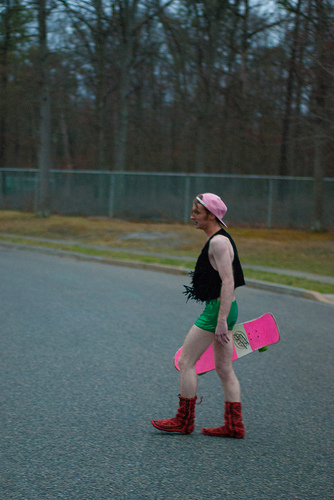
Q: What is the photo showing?
A: It is showing a road.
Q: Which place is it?
A: It is a road.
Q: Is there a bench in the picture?
A: No, there are no benches.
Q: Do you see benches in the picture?
A: No, there are no benches.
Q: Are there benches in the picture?
A: No, there are no benches.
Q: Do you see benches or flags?
A: No, there are no benches or flags.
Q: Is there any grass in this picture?
A: Yes, there is grass.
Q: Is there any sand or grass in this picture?
A: Yes, there is grass.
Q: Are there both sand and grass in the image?
A: No, there is grass but no sand.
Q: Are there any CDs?
A: No, there are no cds.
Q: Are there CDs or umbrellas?
A: No, there are no CDs or umbrellas.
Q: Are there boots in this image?
A: Yes, there are boots.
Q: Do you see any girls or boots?
A: Yes, there are boots.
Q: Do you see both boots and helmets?
A: No, there are boots but no helmets.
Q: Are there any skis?
A: No, there are no skis.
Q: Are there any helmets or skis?
A: No, there are no skis or helmets.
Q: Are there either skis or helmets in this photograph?
A: No, there are no skis or helmets.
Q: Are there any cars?
A: No, there are no cars.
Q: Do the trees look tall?
A: Yes, the trees are tall.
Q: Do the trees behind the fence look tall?
A: Yes, the trees are tall.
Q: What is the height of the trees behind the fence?
A: The trees are tall.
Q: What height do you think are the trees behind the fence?
A: The trees are tall.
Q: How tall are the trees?
A: The trees are tall.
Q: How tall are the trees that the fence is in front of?
A: The trees are tall.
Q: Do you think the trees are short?
A: No, the trees are tall.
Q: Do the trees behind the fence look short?
A: No, the trees are tall.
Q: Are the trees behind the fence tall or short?
A: The trees are tall.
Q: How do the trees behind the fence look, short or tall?
A: The trees are tall.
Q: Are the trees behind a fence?
A: Yes, the trees are behind a fence.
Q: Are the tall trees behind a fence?
A: Yes, the trees are behind a fence.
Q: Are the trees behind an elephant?
A: No, the trees are behind a fence.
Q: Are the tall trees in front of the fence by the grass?
A: No, the trees are behind the fence.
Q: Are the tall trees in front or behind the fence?
A: The trees are behind the fence.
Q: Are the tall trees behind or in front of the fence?
A: The trees are behind the fence.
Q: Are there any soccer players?
A: No, there are no soccer players.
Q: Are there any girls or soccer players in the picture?
A: No, there are no soccer players or girls.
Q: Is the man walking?
A: Yes, the man is walking.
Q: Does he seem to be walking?
A: Yes, the man is walking.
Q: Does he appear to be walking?
A: Yes, the man is walking.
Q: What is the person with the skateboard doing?
A: The man is walking.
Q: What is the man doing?
A: The man is walking.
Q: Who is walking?
A: The man is walking.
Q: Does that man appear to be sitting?
A: No, the man is walking.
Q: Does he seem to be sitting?
A: No, the man is walking.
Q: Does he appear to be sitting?
A: No, the man is walking.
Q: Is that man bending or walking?
A: The man is walking.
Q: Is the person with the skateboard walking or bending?
A: The man is walking.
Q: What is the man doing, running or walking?
A: The man is walking.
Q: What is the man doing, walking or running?
A: The man is walking.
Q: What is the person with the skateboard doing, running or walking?
A: The man is walking.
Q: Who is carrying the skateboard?
A: The man is carrying the skateboard.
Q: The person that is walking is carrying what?
A: The man is carrying a skateboard.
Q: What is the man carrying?
A: The man is carrying a skateboard.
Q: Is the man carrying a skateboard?
A: Yes, the man is carrying a skateboard.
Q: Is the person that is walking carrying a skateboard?
A: Yes, the man is carrying a skateboard.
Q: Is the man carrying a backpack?
A: No, the man is carrying a skateboard.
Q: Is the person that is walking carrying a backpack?
A: No, the man is carrying a skateboard.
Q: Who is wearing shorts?
A: The man is wearing shorts.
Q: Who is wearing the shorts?
A: The man is wearing shorts.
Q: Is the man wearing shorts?
A: Yes, the man is wearing shorts.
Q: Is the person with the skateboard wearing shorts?
A: Yes, the man is wearing shorts.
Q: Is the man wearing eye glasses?
A: No, the man is wearing shorts.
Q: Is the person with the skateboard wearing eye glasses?
A: No, the man is wearing shorts.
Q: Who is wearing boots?
A: The man is wearing boots.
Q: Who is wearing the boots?
A: The man is wearing boots.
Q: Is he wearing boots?
A: Yes, the man is wearing boots.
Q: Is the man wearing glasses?
A: No, the man is wearing boots.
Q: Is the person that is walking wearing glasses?
A: No, the man is wearing boots.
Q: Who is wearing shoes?
A: The man is wearing shoes.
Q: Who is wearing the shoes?
A: The man is wearing shoes.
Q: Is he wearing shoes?
A: Yes, the man is wearing shoes.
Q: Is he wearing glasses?
A: No, the man is wearing shoes.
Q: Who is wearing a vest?
A: The man is wearing a vest.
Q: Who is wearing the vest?
A: The man is wearing a vest.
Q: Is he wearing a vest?
A: Yes, the man is wearing a vest.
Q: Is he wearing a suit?
A: No, the man is wearing a vest.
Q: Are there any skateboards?
A: Yes, there is a skateboard.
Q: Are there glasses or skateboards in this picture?
A: Yes, there is a skateboard.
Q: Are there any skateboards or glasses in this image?
A: Yes, there is a skateboard.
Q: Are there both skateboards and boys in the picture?
A: No, there is a skateboard but no boys.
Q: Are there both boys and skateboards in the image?
A: No, there is a skateboard but no boys.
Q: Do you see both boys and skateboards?
A: No, there is a skateboard but no boys.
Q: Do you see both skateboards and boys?
A: No, there is a skateboard but no boys.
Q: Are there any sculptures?
A: No, there are no sculptures.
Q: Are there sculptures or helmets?
A: No, there are no sculptures or helmets.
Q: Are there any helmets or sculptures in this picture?
A: No, there are no sculptures or helmets.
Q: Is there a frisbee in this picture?
A: No, there are no frisbees.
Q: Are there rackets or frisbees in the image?
A: No, there are no frisbees or rackets.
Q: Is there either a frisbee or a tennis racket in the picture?
A: No, there are no frisbees or rackets.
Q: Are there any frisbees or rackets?
A: No, there are no frisbees or rackets.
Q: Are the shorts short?
A: Yes, the shorts are short.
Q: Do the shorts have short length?
A: Yes, the shorts are short.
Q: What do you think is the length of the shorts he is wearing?
A: The shorts are short.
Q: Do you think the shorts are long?
A: No, the shorts are short.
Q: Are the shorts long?
A: No, the shorts are short.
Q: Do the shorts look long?
A: No, the shorts are short.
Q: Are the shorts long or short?
A: The shorts are short.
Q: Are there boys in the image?
A: No, there are no boys.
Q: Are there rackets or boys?
A: No, there are no boys or rackets.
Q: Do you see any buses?
A: No, there are no buses.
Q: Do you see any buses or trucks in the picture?
A: No, there are no buses or trucks.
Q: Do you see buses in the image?
A: No, there are no buses.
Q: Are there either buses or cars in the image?
A: No, there are no buses or cars.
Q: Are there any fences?
A: Yes, there is a fence.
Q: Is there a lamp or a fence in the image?
A: Yes, there is a fence.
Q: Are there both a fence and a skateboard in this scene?
A: Yes, there are both a fence and a skateboard.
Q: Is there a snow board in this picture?
A: No, there are no snowboards.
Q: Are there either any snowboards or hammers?
A: No, there are no snowboards or hammers.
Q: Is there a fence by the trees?
A: Yes, there is a fence by the trees.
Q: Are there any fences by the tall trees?
A: Yes, there is a fence by the trees.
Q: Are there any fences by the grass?
A: Yes, there is a fence by the grass.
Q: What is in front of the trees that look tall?
A: The fence is in front of the trees.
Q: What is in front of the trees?
A: The fence is in front of the trees.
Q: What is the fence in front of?
A: The fence is in front of the trees.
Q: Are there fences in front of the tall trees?
A: Yes, there is a fence in front of the trees.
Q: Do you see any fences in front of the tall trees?
A: Yes, there is a fence in front of the trees.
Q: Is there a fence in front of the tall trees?
A: Yes, there is a fence in front of the trees.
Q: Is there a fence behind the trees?
A: No, the fence is in front of the trees.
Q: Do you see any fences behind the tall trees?
A: No, the fence is in front of the trees.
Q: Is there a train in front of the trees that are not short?
A: No, there is a fence in front of the trees.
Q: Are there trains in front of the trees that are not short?
A: No, there is a fence in front of the trees.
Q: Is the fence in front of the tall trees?
A: Yes, the fence is in front of the trees.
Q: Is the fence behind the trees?
A: No, the fence is in front of the trees.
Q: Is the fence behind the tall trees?
A: No, the fence is in front of the trees.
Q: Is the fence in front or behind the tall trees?
A: The fence is in front of the trees.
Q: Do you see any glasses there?
A: No, there are no glasses.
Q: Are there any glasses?
A: No, there are no glasses.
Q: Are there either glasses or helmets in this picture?
A: No, there are no glasses or helmets.